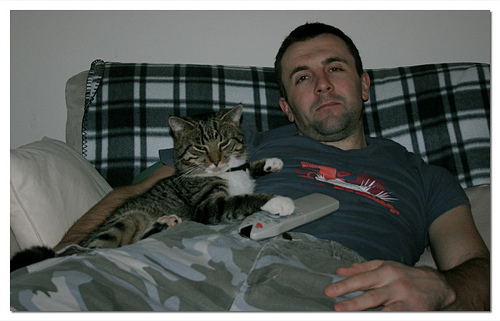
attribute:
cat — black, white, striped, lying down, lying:
[11, 102, 295, 272]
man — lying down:
[9, 22, 491, 312]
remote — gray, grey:
[239, 192, 340, 242]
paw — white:
[193, 192, 295, 226]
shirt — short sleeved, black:
[159, 120, 471, 265]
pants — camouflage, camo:
[9, 220, 382, 312]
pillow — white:
[10, 135, 112, 249]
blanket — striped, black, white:
[82, 57, 492, 189]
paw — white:
[241, 157, 283, 179]